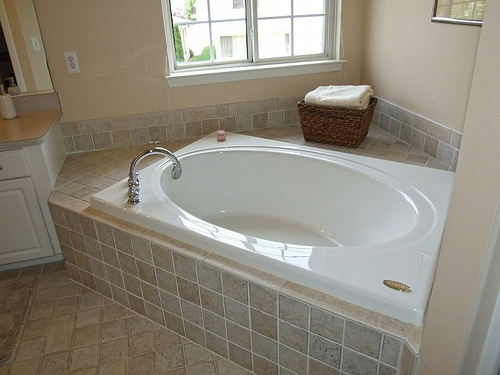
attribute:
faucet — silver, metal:
[129, 145, 182, 203]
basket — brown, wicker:
[299, 97, 375, 147]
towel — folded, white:
[304, 83, 373, 109]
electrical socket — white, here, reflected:
[64, 52, 83, 74]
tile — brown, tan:
[27, 301, 54, 320]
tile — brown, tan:
[200, 287, 224, 313]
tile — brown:
[137, 259, 159, 285]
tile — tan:
[112, 228, 131, 253]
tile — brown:
[79, 216, 99, 237]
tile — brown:
[251, 307, 277, 341]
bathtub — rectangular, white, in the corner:
[88, 130, 455, 326]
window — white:
[165, 2, 334, 69]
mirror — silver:
[0, 23, 20, 88]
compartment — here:
[2, 178, 58, 268]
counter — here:
[1, 110, 62, 145]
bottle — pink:
[217, 130, 225, 141]